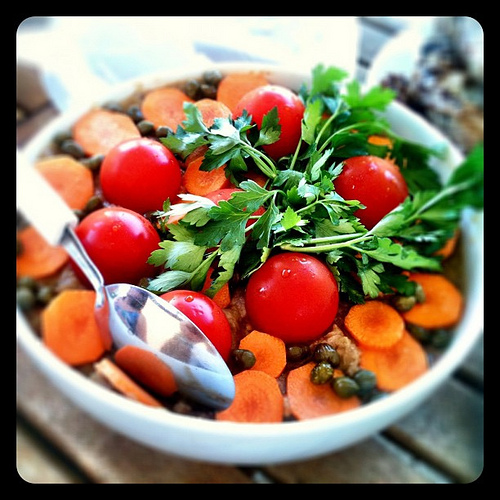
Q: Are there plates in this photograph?
A: No, there are no plates.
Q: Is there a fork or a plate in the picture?
A: No, there are no plates or forks.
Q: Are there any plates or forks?
A: No, there are no plates or forks.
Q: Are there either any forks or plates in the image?
A: No, there are no plates or forks.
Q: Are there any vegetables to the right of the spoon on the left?
A: Yes, there is a vegetable to the right of the spoon.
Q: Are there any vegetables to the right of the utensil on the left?
A: Yes, there is a vegetable to the right of the spoon.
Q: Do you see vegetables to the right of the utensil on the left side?
A: Yes, there is a vegetable to the right of the spoon.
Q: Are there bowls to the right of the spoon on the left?
A: No, there is a vegetable to the right of the spoon.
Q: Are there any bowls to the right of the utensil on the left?
A: No, there is a vegetable to the right of the spoon.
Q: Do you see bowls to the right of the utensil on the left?
A: No, there is a vegetable to the right of the spoon.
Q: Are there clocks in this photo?
A: No, there are no clocks.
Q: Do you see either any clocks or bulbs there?
A: No, there are no clocks or bulbs.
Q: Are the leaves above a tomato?
A: Yes, the leaves are above a tomato.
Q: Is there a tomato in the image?
A: Yes, there is a tomato.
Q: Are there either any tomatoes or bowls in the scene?
A: Yes, there is a tomato.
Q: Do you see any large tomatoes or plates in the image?
A: Yes, there is a large tomato.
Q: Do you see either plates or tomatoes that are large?
A: Yes, the tomato is large.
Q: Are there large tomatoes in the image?
A: Yes, there is a large tomato.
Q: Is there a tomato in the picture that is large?
A: Yes, there is a tomato that is large.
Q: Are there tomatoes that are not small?
A: Yes, there is a large tomato.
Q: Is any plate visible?
A: No, there are no plates.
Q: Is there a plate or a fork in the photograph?
A: No, there are no plates or forks.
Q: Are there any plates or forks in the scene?
A: No, there are no plates or forks.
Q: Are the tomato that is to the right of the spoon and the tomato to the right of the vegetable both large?
A: Yes, both the tomato and the tomato are large.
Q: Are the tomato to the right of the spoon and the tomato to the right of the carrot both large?
A: Yes, both the tomato and the tomato are large.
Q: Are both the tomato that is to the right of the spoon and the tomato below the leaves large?
A: Yes, both the tomato and the tomato are large.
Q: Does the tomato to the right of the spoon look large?
A: Yes, the tomato is large.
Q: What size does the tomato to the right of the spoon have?
A: The tomato has large size.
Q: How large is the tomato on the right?
A: The tomato is large.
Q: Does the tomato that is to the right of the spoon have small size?
A: No, the tomato is large.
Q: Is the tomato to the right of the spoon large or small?
A: The tomato is large.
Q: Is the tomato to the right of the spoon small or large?
A: The tomato is large.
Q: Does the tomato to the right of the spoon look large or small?
A: The tomato is large.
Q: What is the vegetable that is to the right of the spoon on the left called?
A: The vegetable is a tomato.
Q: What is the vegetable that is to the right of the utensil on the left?
A: The vegetable is a tomato.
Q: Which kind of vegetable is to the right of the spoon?
A: The vegetable is a tomato.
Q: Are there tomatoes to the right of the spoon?
A: Yes, there is a tomato to the right of the spoon.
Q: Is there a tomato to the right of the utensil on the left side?
A: Yes, there is a tomato to the right of the spoon.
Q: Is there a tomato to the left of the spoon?
A: No, the tomato is to the right of the spoon.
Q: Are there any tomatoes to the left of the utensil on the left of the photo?
A: No, the tomato is to the right of the spoon.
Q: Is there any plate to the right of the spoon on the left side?
A: No, there is a tomato to the right of the spoon.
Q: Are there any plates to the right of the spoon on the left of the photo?
A: No, there is a tomato to the right of the spoon.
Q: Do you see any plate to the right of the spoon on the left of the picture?
A: No, there is a tomato to the right of the spoon.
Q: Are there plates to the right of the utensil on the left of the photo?
A: No, there is a tomato to the right of the spoon.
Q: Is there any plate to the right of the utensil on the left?
A: No, there is a tomato to the right of the spoon.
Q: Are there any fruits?
A: Yes, there is a fruit.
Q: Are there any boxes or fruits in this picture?
A: Yes, there is a fruit.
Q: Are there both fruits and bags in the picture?
A: No, there is a fruit but no bags.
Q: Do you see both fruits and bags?
A: No, there is a fruit but no bags.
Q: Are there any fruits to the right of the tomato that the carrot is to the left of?
A: Yes, there is a fruit to the right of the tomato.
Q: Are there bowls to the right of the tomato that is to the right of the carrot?
A: No, there is a fruit to the right of the tomato.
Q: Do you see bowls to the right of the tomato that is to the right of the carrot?
A: No, there is a fruit to the right of the tomato.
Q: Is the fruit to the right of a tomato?
A: Yes, the fruit is to the right of a tomato.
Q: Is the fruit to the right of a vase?
A: No, the fruit is to the right of a tomato.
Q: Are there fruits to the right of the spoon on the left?
A: Yes, there is a fruit to the right of the spoon.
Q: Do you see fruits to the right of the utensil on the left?
A: Yes, there is a fruit to the right of the spoon.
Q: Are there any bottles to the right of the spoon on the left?
A: No, there is a fruit to the right of the spoon.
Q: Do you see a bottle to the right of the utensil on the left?
A: No, there is a fruit to the right of the spoon.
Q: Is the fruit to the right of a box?
A: No, the fruit is to the right of a spoon.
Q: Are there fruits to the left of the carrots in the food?
A: Yes, there is a fruit to the left of the carrots.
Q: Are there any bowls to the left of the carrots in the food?
A: No, there is a fruit to the left of the carrots.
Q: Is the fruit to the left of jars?
A: No, the fruit is to the left of the carrots.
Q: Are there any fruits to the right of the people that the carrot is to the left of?
A: Yes, there is a fruit to the right of the people.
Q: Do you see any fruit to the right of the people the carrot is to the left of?
A: Yes, there is a fruit to the right of the people.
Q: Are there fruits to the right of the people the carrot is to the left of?
A: Yes, there is a fruit to the right of the people.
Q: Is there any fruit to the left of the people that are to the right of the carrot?
A: No, the fruit is to the right of the people.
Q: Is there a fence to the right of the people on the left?
A: No, there is a fruit to the right of the people.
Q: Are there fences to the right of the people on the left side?
A: No, there is a fruit to the right of the people.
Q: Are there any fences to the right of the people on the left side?
A: No, there is a fruit to the right of the people.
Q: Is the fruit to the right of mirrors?
A: No, the fruit is to the right of the people.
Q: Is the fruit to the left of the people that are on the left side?
A: No, the fruit is to the right of the people.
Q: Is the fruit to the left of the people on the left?
A: No, the fruit is to the right of the people.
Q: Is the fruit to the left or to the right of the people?
A: The fruit is to the right of the people.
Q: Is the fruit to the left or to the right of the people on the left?
A: The fruit is to the right of the people.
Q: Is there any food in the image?
A: Yes, there is food.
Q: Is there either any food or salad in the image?
A: Yes, there is food.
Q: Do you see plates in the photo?
A: No, there are no plates.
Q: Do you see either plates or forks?
A: No, there are no plates or forks.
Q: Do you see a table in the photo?
A: Yes, there is a table.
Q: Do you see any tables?
A: Yes, there is a table.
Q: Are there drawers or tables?
A: Yes, there is a table.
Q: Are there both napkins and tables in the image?
A: No, there is a table but no napkins.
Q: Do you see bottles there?
A: No, there are no bottles.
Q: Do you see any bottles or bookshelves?
A: No, there are no bottles or bookshelves.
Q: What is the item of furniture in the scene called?
A: The piece of furniture is a table.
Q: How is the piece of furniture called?
A: The piece of furniture is a table.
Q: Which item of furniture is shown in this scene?
A: The piece of furniture is a table.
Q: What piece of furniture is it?
A: The piece of furniture is a table.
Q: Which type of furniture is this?
A: This is a table.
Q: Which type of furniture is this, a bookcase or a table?
A: This is a table.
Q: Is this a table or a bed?
A: This is a table.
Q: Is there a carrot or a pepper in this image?
A: Yes, there is a carrot.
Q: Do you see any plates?
A: No, there are no plates.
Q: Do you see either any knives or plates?
A: No, there are no plates or knives.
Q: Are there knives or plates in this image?
A: No, there are no plates or knives.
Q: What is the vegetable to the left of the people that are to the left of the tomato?
A: The vegetable is a carrot.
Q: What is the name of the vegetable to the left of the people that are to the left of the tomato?
A: The vegetable is a carrot.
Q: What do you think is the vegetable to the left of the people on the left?
A: The vegetable is a carrot.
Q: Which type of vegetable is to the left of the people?
A: The vegetable is a carrot.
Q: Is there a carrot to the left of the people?
A: Yes, there is a carrot to the left of the people.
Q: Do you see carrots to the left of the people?
A: Yes, there is a carrot to the left of the people.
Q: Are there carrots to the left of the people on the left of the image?
A: Yes, there is a carrot to the left of the people.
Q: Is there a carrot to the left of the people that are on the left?
A: Yes, there is a carrot to the left of the people.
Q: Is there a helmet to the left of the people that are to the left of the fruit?
A: No, there is a carrot to the left of the people.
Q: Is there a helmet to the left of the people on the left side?
A: No, there is a carrot to the left of the people.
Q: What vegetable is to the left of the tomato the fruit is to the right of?
A: The vegetable is a carrot.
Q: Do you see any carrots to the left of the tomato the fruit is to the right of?
A: Yes, there is a carrot to the left of the tomato.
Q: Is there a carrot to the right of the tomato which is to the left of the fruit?
A: No, the carrot is to the left of the tomato.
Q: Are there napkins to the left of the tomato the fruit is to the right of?
A: No, there is a carrot to the left of the tomato.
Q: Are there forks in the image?
A: No, there are no forks.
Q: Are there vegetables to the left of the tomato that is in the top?
A: Yes, there is a vegetable to the left of the tomato.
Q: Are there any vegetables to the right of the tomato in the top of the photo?
A: No, the vegetable is to the left of the tomato.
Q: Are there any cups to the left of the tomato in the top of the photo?
A: No, there is a vegetable to the left of the tomato.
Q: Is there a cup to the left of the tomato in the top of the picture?
A: No, there is a vegetable to the left of the tomato.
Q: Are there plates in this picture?
A: No, there are no plates.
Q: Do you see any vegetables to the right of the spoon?
A: Yes, there is a vegetable to the right of the spoon.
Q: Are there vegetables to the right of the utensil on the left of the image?
A: Yes, there is a vegetable to the right of the spoon.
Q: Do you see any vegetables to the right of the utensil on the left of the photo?
A: Yes, there is a vegetable to the right of the spoon.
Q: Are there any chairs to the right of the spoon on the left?
A: No, there is a vegetable to the right of the spoon.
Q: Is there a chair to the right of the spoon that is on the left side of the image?
A: No, there is a vegetable to the right of the spoon.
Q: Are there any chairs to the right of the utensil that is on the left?
A: No, there is a vegetable to the right of the spoon.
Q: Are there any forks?
A: No, there are no forks.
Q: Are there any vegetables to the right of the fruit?
A: Yes, there is a vegetable to the right of the fruit.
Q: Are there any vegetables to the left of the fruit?
A: No, the vegetable is to the right of the fruit.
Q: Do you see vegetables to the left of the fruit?
A: No, the vegetable is to the right of the fruit.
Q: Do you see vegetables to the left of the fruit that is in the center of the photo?
A: No, the vegetable is to the right of the fruit.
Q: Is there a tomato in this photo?
A: Yes, there is a tomato.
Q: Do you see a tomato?
A: Yes, there is a tomato.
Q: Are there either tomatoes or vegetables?
A: Yes, there is a tomato.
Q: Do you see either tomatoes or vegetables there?
A: Yes, there is a tomato.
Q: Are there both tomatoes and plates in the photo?
A: No, there is a tomato but no plates.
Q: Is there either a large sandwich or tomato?
A: Yes, there is a large tomato.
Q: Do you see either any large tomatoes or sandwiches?
A: Yes, there is a large tomato.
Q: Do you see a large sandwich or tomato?
A: Yes, there is a large tomato.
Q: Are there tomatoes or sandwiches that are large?
A: Yes, the tomato is large.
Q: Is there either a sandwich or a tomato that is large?
A: Yes, the tomato is large.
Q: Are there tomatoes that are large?
A: Yes, there is a large tomato.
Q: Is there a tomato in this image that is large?
A: Yes, there is a tomato that is large.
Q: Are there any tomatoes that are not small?
A: Yes, there is a large tomato.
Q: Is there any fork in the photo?
A: No, there are no forks.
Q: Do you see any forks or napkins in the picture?
A: No, there are no forks or napkins.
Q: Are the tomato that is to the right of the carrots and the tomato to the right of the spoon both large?
A: Yes, both the tomato and the tomato are large.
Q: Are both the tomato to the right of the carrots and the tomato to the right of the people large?
A: Yes, both the tomato and the tomato are large.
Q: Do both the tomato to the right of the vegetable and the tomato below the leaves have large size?
A: Yes, both the tomato and the tomato are large.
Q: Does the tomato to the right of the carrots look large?
A: Yes, the tomato is large.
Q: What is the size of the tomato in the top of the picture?
A: The tomato is large.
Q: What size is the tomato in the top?
A: The tomato is large.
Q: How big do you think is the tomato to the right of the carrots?
A: The tomato is large.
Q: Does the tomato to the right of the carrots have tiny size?
A: No, the tomato is large.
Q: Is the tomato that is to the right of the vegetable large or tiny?
A: The tomato is large.